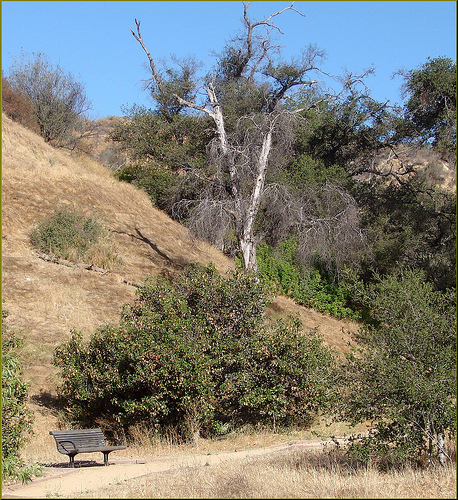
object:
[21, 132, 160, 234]
hill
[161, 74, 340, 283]
tree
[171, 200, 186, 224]
no leaves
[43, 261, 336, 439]
bushy tree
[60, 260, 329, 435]
trees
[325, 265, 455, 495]
trees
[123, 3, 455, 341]
trees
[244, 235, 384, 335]
shrubbery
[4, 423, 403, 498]
dirt path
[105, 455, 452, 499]
vegetation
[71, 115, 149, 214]
valley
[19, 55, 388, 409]
mountain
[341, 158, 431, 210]
tree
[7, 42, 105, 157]
tree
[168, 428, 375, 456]
path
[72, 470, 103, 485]
dirt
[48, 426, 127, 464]
wooden bench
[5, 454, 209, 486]
walkway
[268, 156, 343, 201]
leaves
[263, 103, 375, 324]
tree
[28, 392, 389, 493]
walking trail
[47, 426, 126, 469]
bench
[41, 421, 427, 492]
walk wau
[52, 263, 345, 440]
shrubbery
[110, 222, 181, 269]
shadow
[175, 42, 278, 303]
tree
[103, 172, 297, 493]
bush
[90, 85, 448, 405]
park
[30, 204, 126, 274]
tree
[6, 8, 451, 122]
skies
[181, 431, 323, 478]
dirt track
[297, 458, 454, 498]
grass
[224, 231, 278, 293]
trunk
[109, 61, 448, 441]
forest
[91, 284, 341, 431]
tree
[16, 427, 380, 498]
walking path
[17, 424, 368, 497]
track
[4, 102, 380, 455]
hillside